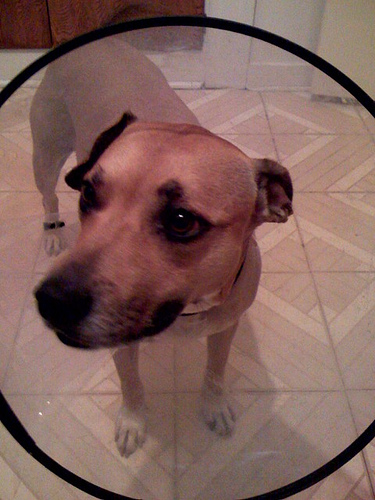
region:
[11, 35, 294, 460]
dog standing on linoleum floor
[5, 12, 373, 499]
black framed cone collar on dog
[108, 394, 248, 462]
two front dog paws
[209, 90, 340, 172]
square shape on linoleum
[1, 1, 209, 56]
wooden planks on wall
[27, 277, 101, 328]
black dog nose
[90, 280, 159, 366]
black dog whiskers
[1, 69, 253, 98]
bottom of door sill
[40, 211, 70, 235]
black objecton dog paw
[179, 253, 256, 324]
black edge of top of cone collar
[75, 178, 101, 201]
The left eye of the dog.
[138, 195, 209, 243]
The right eye of the dog.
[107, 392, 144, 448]
The left front paw of the dog.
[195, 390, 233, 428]
The right front paw on the dog.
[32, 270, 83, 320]
The black nose of the dog.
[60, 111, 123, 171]
The left ear of the dog.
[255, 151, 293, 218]
The right ear of the dog.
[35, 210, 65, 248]
The back paw of the dog.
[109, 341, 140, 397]
The front left leg of the dog.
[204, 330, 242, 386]
The front right leg of the dog.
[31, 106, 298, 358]
the head of a dog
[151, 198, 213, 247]
the eye of a dog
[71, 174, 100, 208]
the eye of a dog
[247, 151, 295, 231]
the ear of a dog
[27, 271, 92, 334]
the nose of a dog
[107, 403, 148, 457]
the paw of a dog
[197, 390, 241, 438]
the paw of a dog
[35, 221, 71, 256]
the paw of a dog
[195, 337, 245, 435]
the leg of a dog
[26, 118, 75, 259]
the hind leg of a dog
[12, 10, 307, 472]
a brown dog indoors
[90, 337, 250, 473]
front legs of dog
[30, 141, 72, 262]
front leg of dog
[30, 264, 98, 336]
nose of dog is black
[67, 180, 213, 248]
eyes of dog are round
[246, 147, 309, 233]
right ear of dog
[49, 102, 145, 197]
left ear of dog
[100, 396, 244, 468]
white paws of dog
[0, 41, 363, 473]
dog on a tiled floor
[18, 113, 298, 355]
head of dog is brown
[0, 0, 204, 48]
wooden closet door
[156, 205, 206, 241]
dog has dark eyes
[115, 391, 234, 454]
two front paws are white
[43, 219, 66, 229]
cuff on the dog's rear paw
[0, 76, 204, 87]
small white floor board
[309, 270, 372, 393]
partial square tile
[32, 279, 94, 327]
dog has a black nose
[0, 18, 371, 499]
safety cone on the dog's head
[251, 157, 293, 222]
the dog's ears are back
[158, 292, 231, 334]
white patch on the dog's chest